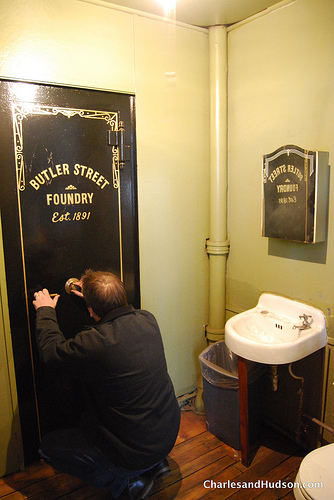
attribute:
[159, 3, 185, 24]
light — on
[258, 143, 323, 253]
cabinet — on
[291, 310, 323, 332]
faucet — silver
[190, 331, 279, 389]
bag — plastic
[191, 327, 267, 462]
trash can — plastic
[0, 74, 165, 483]
wall safe — black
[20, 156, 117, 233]
letters — gold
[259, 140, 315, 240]
mirror — metal 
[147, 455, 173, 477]
shoe — brown and black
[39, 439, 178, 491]
jeans — blue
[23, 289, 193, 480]
jacket — black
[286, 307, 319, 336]
water faucet — silver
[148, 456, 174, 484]
shoe — black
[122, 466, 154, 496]
shoe — black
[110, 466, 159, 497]
shoe — black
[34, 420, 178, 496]
pants — blue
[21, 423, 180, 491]
pants — blue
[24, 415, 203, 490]
jeans — blue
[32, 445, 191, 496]
jeans — blue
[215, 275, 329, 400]
bathroom sink — white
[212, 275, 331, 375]
sink — white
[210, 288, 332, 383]
bathroom sink — white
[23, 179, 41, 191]
letter — beige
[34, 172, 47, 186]
letter — beige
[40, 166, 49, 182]
letter — beige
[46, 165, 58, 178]
letter — beige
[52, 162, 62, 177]
letter — beige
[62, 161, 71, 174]
letter — beige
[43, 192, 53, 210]
letter — beige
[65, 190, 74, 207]
letter — beige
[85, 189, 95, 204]
letter — beige